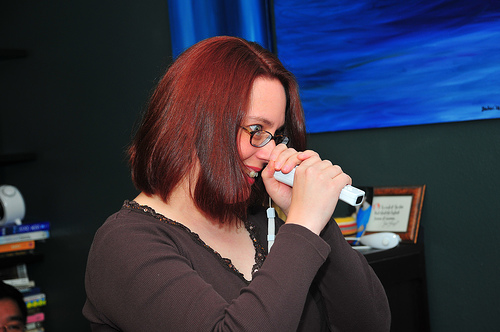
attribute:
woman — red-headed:
[75, 28, 398, 330]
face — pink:
[212, 73, 292, 212]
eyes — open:
[245, 122, 266, 138]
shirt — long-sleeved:
[85, 175, 391, 330]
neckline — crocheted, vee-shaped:
[118, 188, 271, 284]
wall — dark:
[4, 5, 495, 330]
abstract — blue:
[165, 3, 497, 161]